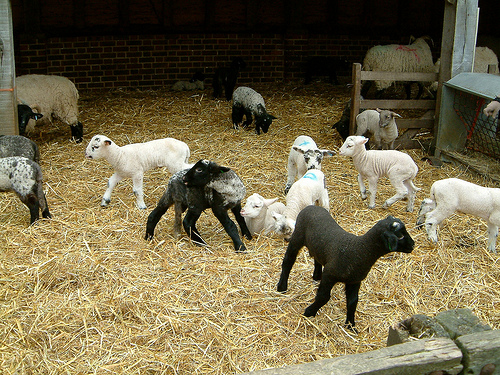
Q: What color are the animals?
A: Black, white and gray.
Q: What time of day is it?
A: Daytime.